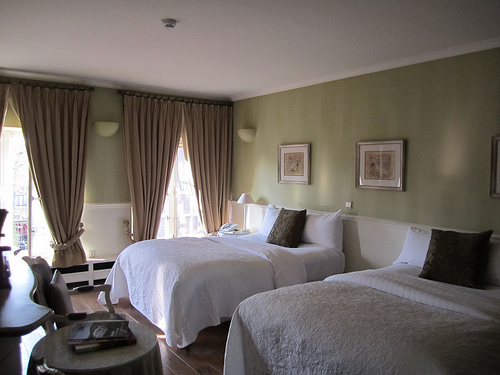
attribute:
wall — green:
[230, 46, 500, 239]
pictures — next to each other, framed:
[276, 139, 410, 194]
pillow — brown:
[419, 227, 494, 292]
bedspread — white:
[224, 263, 499, 374]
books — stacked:
[66, 318, 137, 354]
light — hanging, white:
[93, 118, 121, 138]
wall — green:
[0, 74, 237, 295]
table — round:
[205, 229, 252, 240]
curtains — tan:
[1, 78, 238, 269]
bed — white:
[221, 226, 499, 374]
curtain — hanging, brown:
[1, 83, 94, 269]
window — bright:
[3, 126, 31, 254]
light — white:
[236, 126, 258, 145]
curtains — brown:
[122, 92, 234, 245]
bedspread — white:
[95, 235, 305, 349]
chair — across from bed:
[22, 255, 127, 338]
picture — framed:
[275, 143, 312, 187]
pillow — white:
[302, 209, 347, 251]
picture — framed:
[487, 131, 499, 201]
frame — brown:
[354, 137, 408, 195]